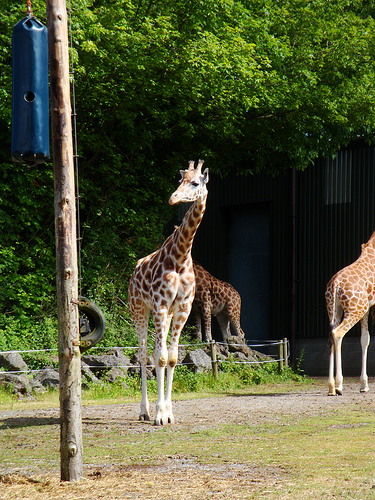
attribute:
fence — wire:
[4, 342, 291, 367]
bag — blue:
[12, 16, 54, 159]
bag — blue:
[7, 12, 56, 166]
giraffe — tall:
[153, 155, 214, 335]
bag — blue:
[13, 15, 60, 159]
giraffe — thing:
[129, 159, 213, 425]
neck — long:
[168, 198, 208, 256]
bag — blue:
[10, 29, 78, 158]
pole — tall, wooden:
[43, 0, 89, 478]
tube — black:
[68, 292, 108, 354]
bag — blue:
[7, 1, 51, 166]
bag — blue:
[12, 13, 61, 168]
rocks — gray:
[4, 344, 264, 398]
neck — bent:
[171, 199, 205, 275]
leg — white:
[165, 363, 173, 426]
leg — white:
[154, 366, 164, 423]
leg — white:
[140, 364, 150, 420]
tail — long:
[330, 280, 340, 329]